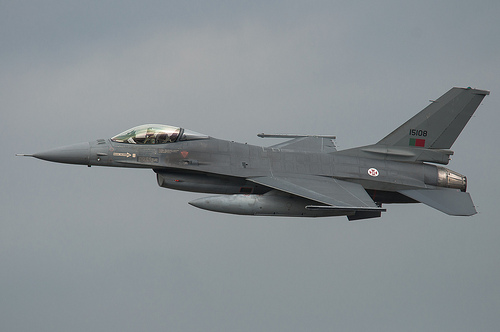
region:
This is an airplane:
[10, 48, 495, 237]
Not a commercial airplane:
[18, 37, 498, 253]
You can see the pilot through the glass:
[117, 122, 180, 144]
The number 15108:
[394, 115, 431, 140]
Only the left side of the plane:
[27, 64, 482, 231]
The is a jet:
[23, 63, 493, 238]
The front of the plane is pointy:
[5, 128, 57, 177]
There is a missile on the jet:
[182, 182, 302, 222]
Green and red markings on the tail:
[403, 126, 431, 151]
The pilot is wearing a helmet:
[140, 112, 169, 144]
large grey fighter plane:
[31, 80, 499, 212]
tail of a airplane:
[392, 80, 483, 228]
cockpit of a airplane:
[100, 111, 193, 163]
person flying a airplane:
[121, 120, 183, 175]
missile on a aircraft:
[194, 183, 366, 229]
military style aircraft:
[25, 98, 485, 216]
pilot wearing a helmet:
[141, 125, 159, 144]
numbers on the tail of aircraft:
[400, 115, 464, 158]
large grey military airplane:
[18, 86, 497, 224]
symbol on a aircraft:
[361, 168, 381, 178]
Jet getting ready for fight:
[66, 9, 396, 323]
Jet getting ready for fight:
[53, 36, 416, 325]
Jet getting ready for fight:
[61, 39, 410, 255]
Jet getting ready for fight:
[103, 98, 464, 329]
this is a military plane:
[19, 75, 487, 222]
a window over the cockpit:
[107, 120, 210, 151]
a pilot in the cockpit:
[144, 125, 158, 145]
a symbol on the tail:
[407, 135, 427, 149]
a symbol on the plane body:
[365, 167, 383, 177]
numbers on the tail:
[406, 125, 431, 138]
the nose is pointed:
[6, 144, 39, 161]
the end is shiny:
[435, 162, 467, 197]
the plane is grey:
[12, 78, 496, 219]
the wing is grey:
[257, 130, 344, 154]